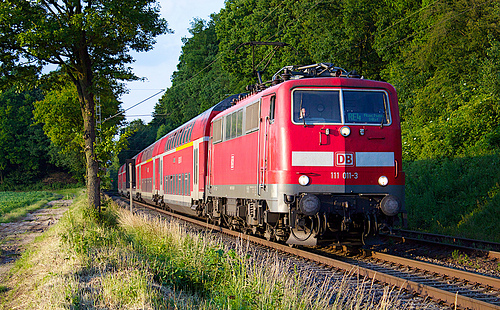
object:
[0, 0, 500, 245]
forest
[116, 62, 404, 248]
train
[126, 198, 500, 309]
railroad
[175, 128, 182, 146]
train window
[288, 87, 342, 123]
window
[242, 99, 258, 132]
window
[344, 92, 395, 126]
window